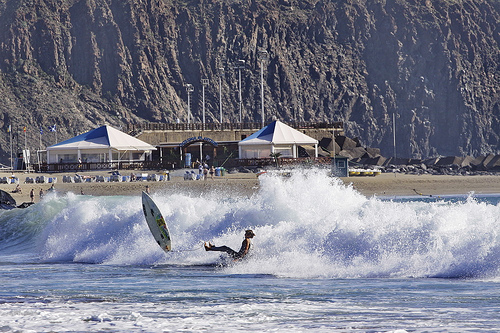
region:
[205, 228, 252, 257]
person fell off the board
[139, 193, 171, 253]
a surfboard in the air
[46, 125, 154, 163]
a white top tent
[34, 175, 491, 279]
a large wave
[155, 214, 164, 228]
stickers on the board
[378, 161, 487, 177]
rocks on the beach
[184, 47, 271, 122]
tall white light posts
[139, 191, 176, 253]
a white surfboard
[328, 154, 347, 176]
a small shed on the beach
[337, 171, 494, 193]
sand on the beach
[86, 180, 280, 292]
The surfboard is upright.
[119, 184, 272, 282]
The person in the water is wearing a leg leash.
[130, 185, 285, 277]
The person in the water has fallen off the surfboard.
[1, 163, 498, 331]
The water is splashing.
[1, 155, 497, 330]
The water is wavy.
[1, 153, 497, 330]
The water is choppy.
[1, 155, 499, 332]
The water is rugged.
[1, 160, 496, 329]
The water is boisterous.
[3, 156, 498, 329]
The water is rambunctious.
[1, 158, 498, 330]
The water is powerful.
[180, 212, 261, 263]
surfer falling from board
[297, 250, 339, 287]
white and blue ocean waves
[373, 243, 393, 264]
white and blue ocean waves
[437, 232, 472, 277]
white and blue ocean waves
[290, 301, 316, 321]
white and blue ocean waves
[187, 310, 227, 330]
white and blue ocean waves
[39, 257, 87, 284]
white and blue ocean waves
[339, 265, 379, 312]
white and blue ocean waves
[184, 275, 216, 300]
white and blue ocean waves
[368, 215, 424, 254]
white and blue ocean waves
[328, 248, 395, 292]
white and blue ocean waves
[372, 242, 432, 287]
white and blue ocean waves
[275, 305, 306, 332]
white and blue ocean waves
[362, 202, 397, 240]
white and blue ocean waves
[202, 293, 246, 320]
white and blue ocean waves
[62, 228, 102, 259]
white and blue ocean waves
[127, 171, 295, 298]
a surfer who just fell off the surfboard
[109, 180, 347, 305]
surfer who fell off surfboard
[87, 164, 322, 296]
surfer who fell off surfboard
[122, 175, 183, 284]
a surfboard in midair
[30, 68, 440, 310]
a person who came seperated from their surfboard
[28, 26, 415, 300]
a surfer at a beach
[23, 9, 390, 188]
a building on a beach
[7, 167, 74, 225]
people at a beach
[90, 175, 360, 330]
a surfer whose board came loose